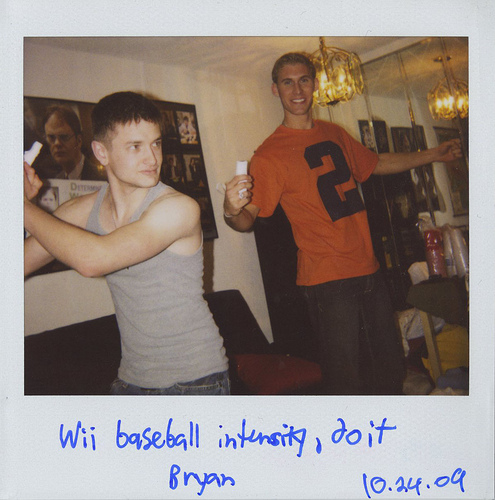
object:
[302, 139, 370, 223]
2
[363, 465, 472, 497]
date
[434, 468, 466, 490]
handwriting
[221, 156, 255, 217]
controller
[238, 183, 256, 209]
wii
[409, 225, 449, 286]
cups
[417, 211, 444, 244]
stack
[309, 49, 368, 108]
lights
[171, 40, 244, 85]
ceiling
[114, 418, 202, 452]
words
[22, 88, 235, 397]
man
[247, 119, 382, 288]
shirt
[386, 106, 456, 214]
mirrors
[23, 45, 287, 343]
wall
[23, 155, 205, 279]
batter stand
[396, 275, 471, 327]
table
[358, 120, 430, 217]
mirror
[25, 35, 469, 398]
picture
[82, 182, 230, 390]
tank top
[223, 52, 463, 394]
man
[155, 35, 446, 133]
room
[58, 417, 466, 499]
text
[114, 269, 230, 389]
undershirt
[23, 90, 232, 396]
men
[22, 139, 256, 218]
controllers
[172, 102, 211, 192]
images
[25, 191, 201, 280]
arms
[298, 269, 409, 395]
pants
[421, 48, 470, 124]
chandler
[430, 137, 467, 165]
hand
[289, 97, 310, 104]
mouth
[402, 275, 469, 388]
shelf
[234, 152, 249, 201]
remote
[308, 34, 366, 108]
chandelier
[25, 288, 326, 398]
sofa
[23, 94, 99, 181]
picture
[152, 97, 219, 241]
frame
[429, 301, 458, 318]
tablecloth